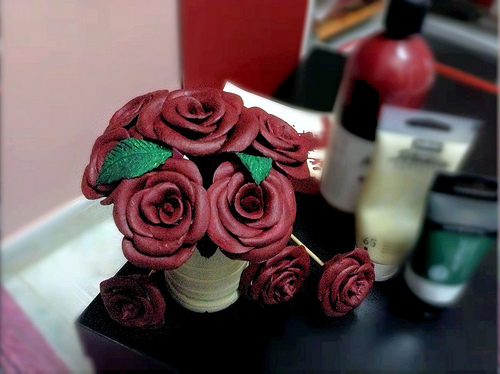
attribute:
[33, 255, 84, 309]
floor — white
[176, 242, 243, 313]
vase — white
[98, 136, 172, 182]
leaf — green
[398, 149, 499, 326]
paint — green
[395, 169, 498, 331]
paint tube — dark, green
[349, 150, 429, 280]
bottle — yellow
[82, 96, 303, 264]
roses — red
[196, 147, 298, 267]
clay rose — red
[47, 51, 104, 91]
wall — pink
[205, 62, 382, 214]
paper — white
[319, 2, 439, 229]
bottle — Red 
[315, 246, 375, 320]
rose — Red 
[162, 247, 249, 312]
vase — white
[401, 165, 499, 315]
tube — yellow 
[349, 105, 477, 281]
tube — off white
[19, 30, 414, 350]
clay roses — Small 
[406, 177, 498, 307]
tube — Green , black 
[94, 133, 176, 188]
leaf — Green 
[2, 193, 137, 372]
rug — Pink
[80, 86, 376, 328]
roses — fake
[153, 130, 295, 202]
leaves — green 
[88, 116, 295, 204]
leaves — green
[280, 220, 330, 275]
stem — Stick